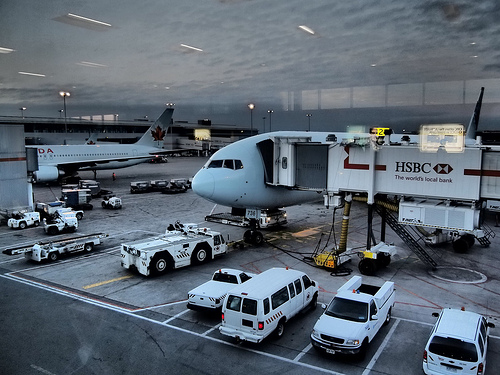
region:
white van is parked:
[426, 309, 494, 374]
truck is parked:
[304, 255, 396, 356]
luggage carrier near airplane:
[124, 201, 225, 279]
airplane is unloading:
[154, 92, 498, 230]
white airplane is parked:
[26, 97, 188, 197]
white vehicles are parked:
[117, 220, 498, 371]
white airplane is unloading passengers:
[147, 99, 497, 225]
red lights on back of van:
[219, 308, 266, 330]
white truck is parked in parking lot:
[306, 269, 398, 366]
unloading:
[277, 121, 494, 227]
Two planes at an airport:
[26, 77, 486, 242]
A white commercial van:
[214, 262, 327, 342]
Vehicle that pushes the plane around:
[105, 210, 225, 276]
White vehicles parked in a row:
[153, 252, 492, 364]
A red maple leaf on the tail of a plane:
[141, 120, 171, 150]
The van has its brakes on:
[207, 299, 277, 341]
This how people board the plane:
[257, 122, 492, 212]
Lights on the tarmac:
[241, 95, 263, 131]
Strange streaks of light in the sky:
[20, 3, 338, 75]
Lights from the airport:
[263, 69, 483, 105]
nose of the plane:
[179, 128, 257, 205]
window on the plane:
[199, 148, 252, 177]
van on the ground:
[216, 244, 323, 366]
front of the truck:
[308, 326, 360, 358]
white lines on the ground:
[148, 305, 185, 343]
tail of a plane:
[136, 105, 188, 154]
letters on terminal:
[388, 155, 435, 181]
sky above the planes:
[177, 10, 260, 64]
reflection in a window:
[49, 0, 118, 62]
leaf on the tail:
[138, 118, 175, 153]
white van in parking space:
[222, 266, 320, 340]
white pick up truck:
[311, 278, 394, 355]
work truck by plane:
[118, 223, 228, 273]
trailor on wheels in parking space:
[4, 233, 111, 264]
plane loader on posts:
[279, 139, 499, 200]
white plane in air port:
[191, 91, 485, 207]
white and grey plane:
[28, 105, 174, 177]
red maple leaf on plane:
[150, 125, 167, 143]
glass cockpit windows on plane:
[207, 159, 243, 169]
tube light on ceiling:
[182, 42, 204, 54]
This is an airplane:
[176, 84, 344, 263]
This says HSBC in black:
[395, 150, 482, 200]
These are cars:
[132, 260, 367, 367]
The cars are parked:
[210, 224, 400, 369]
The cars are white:
[251, 238, 409, 367]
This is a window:
[336, 306, 383, 333]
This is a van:
[206, 237, 322, 372]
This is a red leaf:
[133, 100, 207, 175]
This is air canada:
[21, 130, 91, 211]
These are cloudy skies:
[236, 21, 362, 100]